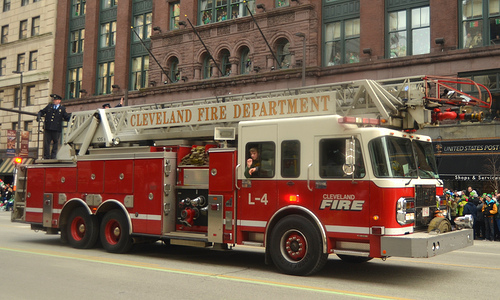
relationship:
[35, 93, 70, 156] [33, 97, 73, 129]
fireman wearing jacket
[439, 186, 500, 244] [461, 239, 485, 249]
people standing on sidewalk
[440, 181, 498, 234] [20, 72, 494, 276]
people watching fire truck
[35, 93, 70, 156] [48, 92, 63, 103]
fireman has hat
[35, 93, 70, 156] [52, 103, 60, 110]
fireman wears shirt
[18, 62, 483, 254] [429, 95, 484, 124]
ladder at end of hose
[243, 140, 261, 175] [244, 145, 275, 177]
person waving out of window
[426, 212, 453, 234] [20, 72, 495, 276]
hose on fire truck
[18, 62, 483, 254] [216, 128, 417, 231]
ladder on truck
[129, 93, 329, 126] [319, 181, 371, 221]
writing on sign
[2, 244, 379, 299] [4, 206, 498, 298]
lines on street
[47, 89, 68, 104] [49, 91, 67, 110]
hat on head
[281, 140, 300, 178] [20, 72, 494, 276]
window on fire truck